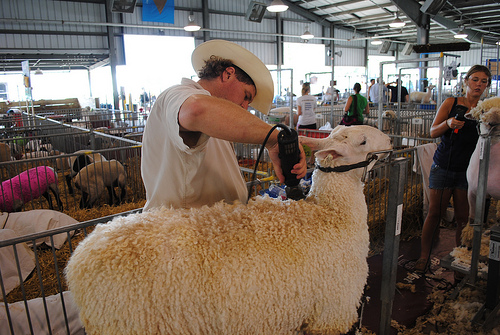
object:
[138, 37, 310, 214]
man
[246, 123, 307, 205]
electric shears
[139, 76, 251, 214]
shirt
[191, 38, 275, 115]
hat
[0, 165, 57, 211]
blanket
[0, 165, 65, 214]
sheep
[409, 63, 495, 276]
woman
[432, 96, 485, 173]
tank top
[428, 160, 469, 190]
shorts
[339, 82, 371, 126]
woman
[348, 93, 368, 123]
shirt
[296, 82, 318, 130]
woman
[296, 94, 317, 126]
shirt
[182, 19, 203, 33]
lights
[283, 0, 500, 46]
ceiling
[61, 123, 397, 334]
sheep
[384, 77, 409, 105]
woman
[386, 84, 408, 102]
shirt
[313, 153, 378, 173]
harness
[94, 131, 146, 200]
gate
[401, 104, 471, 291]
electric shears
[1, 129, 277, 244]
holding pen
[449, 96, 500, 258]
sheep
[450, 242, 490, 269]
wool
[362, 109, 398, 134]
sheep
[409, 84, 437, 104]
sheep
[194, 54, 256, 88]
hair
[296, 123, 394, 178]
head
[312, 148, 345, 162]
ear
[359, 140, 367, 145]
eye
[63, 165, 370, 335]
wool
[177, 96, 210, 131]
elbow